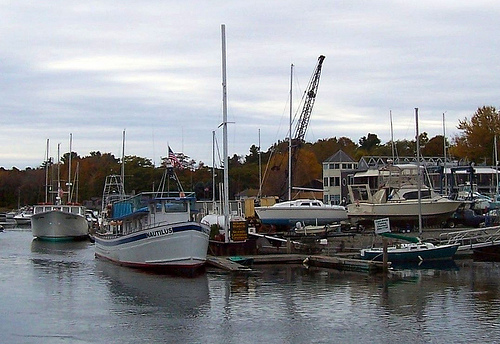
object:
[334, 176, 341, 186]
window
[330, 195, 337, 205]
window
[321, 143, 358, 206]
building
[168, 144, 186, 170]
flag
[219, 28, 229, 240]
mast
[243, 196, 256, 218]
building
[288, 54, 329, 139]
crane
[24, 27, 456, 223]
background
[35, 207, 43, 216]
windows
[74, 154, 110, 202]
trees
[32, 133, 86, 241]
boat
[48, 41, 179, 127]
sky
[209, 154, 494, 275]
dock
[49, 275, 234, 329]
water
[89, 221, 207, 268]
boat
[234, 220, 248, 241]
barrel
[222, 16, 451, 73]
skies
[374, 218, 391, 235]
sign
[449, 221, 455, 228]
wheels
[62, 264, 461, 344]
body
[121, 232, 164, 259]
side